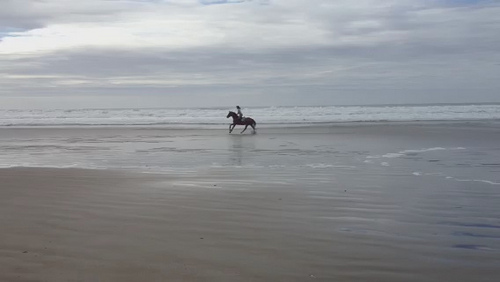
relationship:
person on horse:
[230, 101, 248, 119] [214, 91, 276, 139]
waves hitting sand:
[9, 112, 499, 155] [1, 118, 497, 278]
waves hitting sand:
[0, 102, 500, 148] [7, 168, 497, 278]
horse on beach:
[226, 110, 258, 134] [46, 145, 465, 265]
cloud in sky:
[3, 3, 411, 69] [2, 1, 498, 106]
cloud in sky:
[0, 0, 500, 63] [2, 1, 498, 106]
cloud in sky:
[0, 0, 500, 63] [1, 12, 498, 104]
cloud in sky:
[0, 0, 500, 63] [5, 7, 488, 129]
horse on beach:
[220, 102, 260, 142] [1, 158, 499, 276]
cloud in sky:
[0, 0, 500, 63] [154, 29, 311, 52]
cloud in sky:
[0, 0, 500, 63] [292, 39, 456, 101]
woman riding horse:
[235, 103, 242, 117] [227, 111, 259, 132]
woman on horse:
[235, 105, 243, 119] [221, 109, 262, 134]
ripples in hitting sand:
[311, 160, 441, 259] [0, 165, 500, 282]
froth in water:
[362, 145, 464, 155] [0, 103, 498, 280]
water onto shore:
[0, 107, 498, 177] [3, 171, 499, 278]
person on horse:
[235, 106, 244, 120] [226, 110, 256, 133]